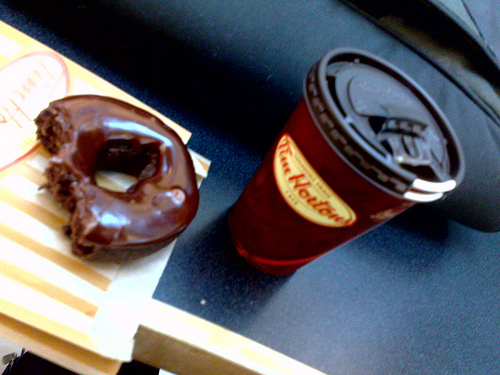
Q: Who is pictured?
A: No one.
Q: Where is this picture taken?
A: Desk.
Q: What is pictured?
A: Coffee and donut.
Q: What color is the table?
A: Blue.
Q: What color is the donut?
A: Brown.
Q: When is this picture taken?
A: While eating.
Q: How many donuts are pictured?
A: One.